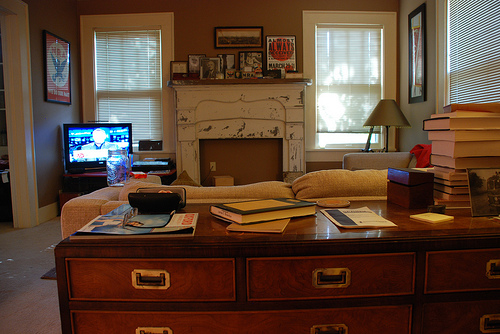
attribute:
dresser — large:
[55, 201, 498, 330]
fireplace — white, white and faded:
[171, 77, 311, 193]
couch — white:
[55, 168, 394, 241]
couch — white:
[61, 168, 434, 240]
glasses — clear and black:
[116, 205, 183, 229]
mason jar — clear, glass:
[104, 143, 135, 188]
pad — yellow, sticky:
[408, 201, 449, 219]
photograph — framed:
[212, 25, 268, 51]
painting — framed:
[386, 5, 436, 108]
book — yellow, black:
[222, 187, 346, 227]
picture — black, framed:
[393, 13, 443, 112]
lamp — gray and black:
[361, 98, 412, 152]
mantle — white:
[170, 70, 319, 198]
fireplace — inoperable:
[199, 138, 281, 187]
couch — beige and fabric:
[52, 158, 442, 265]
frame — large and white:
[86, 72, 178, 118]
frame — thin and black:
[42, 99, 59, 175]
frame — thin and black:
[256, 53, 299, 106]